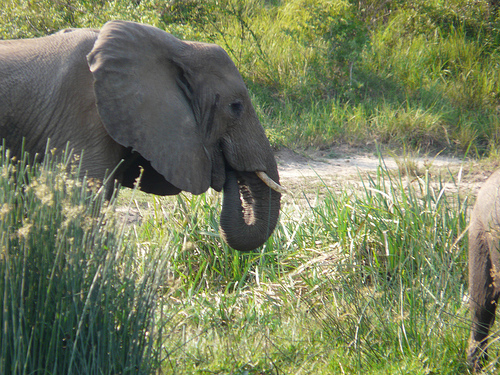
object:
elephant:
[0, 20, 288, 251]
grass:
[341, 288, 423, 374]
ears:
[90, 19, 215, 194]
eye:
[228, 102, 243, 118]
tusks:
[254, 168, 289, 204]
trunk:
[221, 170, 279, 250]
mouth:
[215, 160, 251, 192]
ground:
[30, 254, 464, 374]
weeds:
[349, 168, 466, 296]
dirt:
[294, 170, 320, 187]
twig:
[291, 146, 341, 168]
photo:
[23, 29, 495, 324]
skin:
[13, 94, 58, 133]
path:
[263, 149, 500, 194]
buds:
[49, 211, 82, 238]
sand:
[275, 147, 393, 169]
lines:
[35, 82, 69, 168]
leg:
[456, 204, 500, 368]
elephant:
[460, 167, 500, 371]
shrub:
[44, 166, 171, 367]